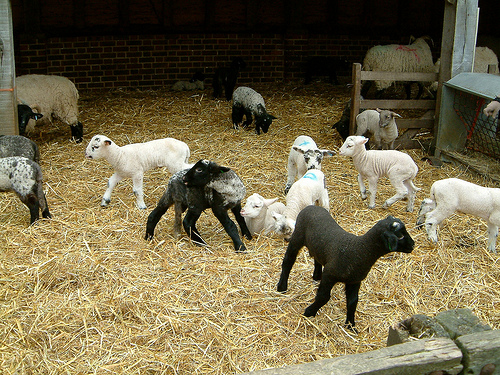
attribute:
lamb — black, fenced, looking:
[277, 204, 415, 329]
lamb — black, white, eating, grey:
[231, 84, 278, 133]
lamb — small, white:
[85, 134, 193, 210]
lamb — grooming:
[285, 135, 335, 193]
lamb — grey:
[1, 156, 52, 225]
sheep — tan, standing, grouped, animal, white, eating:
[365, 33, 436, 99]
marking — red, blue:
[394, 42, 423, 66]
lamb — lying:
[239, 192, 278, 241]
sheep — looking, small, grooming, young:
[146, 160, 252, 251]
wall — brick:
[15, 32, 498, 86]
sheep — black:
[211, 55, 246, 104]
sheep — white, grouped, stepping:
[340, 135, 419, 214]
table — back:
[431, 72, 500, 185]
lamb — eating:
[282, 167, 331, 243]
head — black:
[258, 112, 274, 134]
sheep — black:
[303, 57, 352, 88]